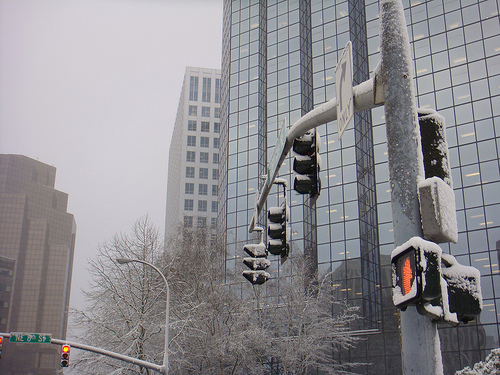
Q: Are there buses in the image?
A: No, there are no buses.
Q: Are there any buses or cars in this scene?
A: No, there are no buses or cars.